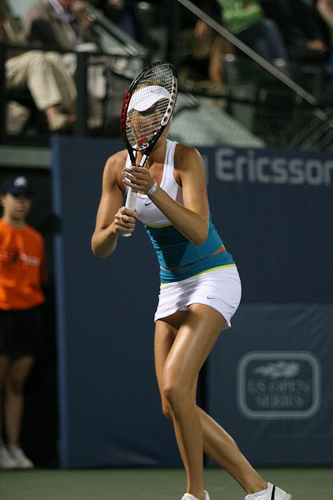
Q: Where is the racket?
A: Hand.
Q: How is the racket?
A: Red and black.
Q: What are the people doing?
A: Sititng down.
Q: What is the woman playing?
A: Tennis.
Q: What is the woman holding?
A: Racquet.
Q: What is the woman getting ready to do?
A: Hit the ball.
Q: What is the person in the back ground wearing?
A: Orange shirt.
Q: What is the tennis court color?
A: Green.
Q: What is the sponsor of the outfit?
A: Nike.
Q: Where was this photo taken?
A: On a field.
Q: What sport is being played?
A: Tennis.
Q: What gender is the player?
A: Female.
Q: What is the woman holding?
A: A tennis racket.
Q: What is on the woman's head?
A: A sun visor.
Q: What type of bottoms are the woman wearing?
A: A skirt.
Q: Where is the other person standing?
A: Near the wall.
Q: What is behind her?
A: Wall.